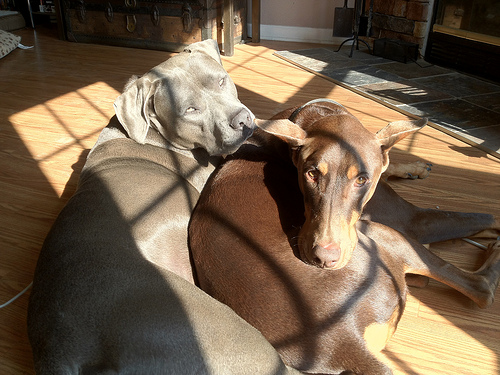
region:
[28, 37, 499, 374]
Dogs lying on floor.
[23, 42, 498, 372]
Sun is shining on dogs.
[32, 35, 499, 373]
Both dogs are brown.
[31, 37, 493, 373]
One dog has darker fur than the other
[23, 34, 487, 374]
Both dogs are shorthairs.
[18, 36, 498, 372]
Dogs are looking at the camera.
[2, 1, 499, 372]
Floor is hardwood laminant.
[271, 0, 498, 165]
Ceramic tile in front of fireplace.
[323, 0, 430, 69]
Fireplace tools beside fireplace.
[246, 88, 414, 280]
Dog's ears are raised.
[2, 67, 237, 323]
shadow is cast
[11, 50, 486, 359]
the weather is sunny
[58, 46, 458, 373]
the dogs are two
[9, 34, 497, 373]
it is a daytime scene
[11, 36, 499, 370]
it is an indoor scene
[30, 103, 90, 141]
floor is made of wood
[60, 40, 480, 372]
dogs are lying down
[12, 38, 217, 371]
the left dog is black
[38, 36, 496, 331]
it is in a house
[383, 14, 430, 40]
the wall is made of bricks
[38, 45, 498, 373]
Two dogs lying together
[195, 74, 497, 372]
Dog is brown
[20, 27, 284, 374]
Dog is grey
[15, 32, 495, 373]
Dogs lying on a wooden floor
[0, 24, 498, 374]
Floor is light brown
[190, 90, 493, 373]
Dogs have neck turned to the right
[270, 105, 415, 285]
Dog rest head on side of body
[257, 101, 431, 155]
Dog's ears are light brown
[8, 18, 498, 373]
Sun light over the body of dogs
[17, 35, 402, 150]
Sand cast shadow of window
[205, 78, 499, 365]
a young brown doberman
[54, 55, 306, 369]
a brownish grey bully breed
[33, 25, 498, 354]
two short haired canines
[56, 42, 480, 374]
two dogs laying in the sun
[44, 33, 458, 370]
two large breeds cuddling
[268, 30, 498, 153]
slate tile on the floor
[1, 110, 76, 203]
hard wood floors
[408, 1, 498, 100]
a fire place in the corner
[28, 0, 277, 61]
a large wooden chest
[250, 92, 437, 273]
a curious face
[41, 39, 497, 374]
two dogs are lying on the floor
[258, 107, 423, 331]
the dog is brown in color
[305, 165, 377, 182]
the dogs eyes are opened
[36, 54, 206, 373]
the dog is grey in color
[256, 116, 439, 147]
the dogs eyes are wide apart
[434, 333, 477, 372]
the sun is shining outside shown by rays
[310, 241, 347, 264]
the dog has a brown nose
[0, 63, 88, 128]
the floor is made of wood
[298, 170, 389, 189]
the dog is staring at the camera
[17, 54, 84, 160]
the floor is brown in color